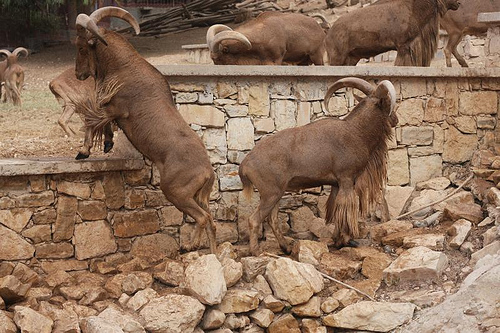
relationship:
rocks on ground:
[1, 260, 436, 332] [0, 25, 241, 164]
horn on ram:
[373, 80, 397, 117] [237, 76, 399, 257]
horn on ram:
[322, 75, 375, 112] [237, 76, 399, 257]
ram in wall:
[237, 76, 399, 257] [0, 11, 499, 280]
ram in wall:
[56, 4, 226, 256] [0, 11, 499, 280]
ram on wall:
[74, 6, 219, 257] [16, 63, 475, 258]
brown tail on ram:
[236, 169, 253, 197] [236, 78, 408, 248]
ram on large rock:
[237, 76, 399, 257] [182, 253, 227, 305]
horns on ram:
[72, 6, 151, 39] [74, 6, 219, 257]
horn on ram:
[210, 30, 253, 54] [206, 10, 327, 65]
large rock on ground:
[177, 254, 236, 310] [4, 238, 495, 331]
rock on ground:
[321, 300, 413, 331] [2, 185, 497, 332]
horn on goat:
[320, 75, 376, 117] [198, 62, 439, 222]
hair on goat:
[322, 121, 394, 236] [238, 76, 398, 256]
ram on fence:
[74, 6, 219, 257] [2, 38, 492, 274]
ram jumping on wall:
[56, 4, 226, 256] [152, 49, 284, 169]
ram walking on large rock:
[236, 78, 408, 248] [381, 245, 449, 288]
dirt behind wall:
[19, 77, 51, 137] [125, 56, 497, 234]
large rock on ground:
[371, 246, 443, 286] [66, 241, 498, 331]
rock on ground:
[132, 286, 206, 331] [342, 223, 493, 305]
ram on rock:
[237, 76, 399, 257] [70, 212, 428, 312]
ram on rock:
[74, 6, 219, 257] [70, 212, 428, 312]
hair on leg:
[339, 176, 388, 236] [324, 182, 353, 249]